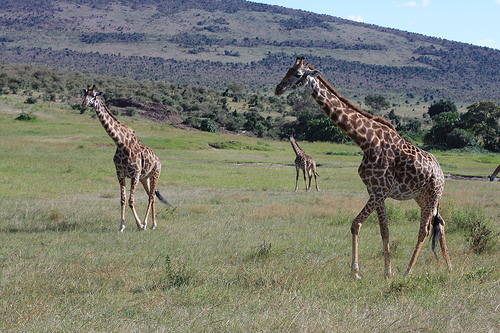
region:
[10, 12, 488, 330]
giraffes in a field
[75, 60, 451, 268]
three giraffes in a field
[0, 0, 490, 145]
large mountain with shrubs on it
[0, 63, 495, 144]
shrubs and trees at the base of the mountain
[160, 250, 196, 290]
patch of tall grass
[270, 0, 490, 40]
blue sky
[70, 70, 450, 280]
the three giraffes are looking in the same direction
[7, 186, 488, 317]
dry grass in the field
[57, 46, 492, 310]
giraffes in the field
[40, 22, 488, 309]
giraffes in the field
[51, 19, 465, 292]
giraffes in the field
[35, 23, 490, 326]
giraffes in the field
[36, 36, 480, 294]
giraffes in the field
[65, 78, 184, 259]
the giraffe is brown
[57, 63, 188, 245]
the giraffe is brown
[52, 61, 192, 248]
the giraffe is brown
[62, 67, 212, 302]
the giraffe is brown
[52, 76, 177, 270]
the giraffe is brown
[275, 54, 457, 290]
the giraffe is walking by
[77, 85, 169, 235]
the giraffe is walking by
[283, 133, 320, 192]
the giraffe is walking by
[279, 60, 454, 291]
the giraffe is brown and white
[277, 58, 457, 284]
the giraffe is looking left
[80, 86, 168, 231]
the giraffe is heading left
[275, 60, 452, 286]
the giraffe is taking a step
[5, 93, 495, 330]
the field is full of grass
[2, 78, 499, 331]
the grass is green in color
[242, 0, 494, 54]
the sky is clear and blue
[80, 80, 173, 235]
a giraffe in a green plain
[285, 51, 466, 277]
a giraffe in a green plain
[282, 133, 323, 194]
a giraffe in a green plain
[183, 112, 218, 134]
green bushes on a hill side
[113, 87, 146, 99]
green bushes on a hill side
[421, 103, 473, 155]
green bushes on a hill side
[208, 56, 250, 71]
green bushes on a hill side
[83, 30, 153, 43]
green bushes on a hill side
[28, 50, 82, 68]
green bushes on a hill side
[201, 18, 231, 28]
green bushes on a hill side